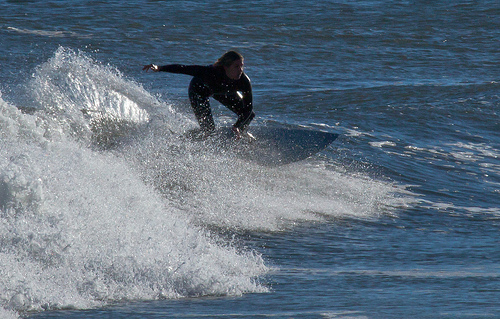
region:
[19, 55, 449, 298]
The wave is breaking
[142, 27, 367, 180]
Person surfing in the ocean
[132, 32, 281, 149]
Person wearing a wet suit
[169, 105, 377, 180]
Surfboard is blue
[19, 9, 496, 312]
The water is blue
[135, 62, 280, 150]
The wet suit is black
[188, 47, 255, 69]
Surfer has long hair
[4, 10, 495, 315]
Photo taken during the day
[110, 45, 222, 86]
Right arm is outstretched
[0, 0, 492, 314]
It's a sunny day out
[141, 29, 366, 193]
a person surfing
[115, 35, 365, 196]
a person on a surfboard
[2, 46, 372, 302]
the waves are large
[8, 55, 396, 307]
the waves are white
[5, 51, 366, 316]
waves in the ocean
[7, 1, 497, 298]
the ocean is undulating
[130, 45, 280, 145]
the person wearing a wetsuit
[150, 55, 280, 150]
the wetsuit is dark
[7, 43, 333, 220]
the waves are splashing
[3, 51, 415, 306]
the waves are frothy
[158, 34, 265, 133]
man is on surfboard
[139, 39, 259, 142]
man wears black swimsuit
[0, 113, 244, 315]
man rides choppy wave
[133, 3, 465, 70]
water is calm behind wave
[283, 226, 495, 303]
water is calm in front of wave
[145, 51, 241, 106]
right arm is outstretched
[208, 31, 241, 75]
man has light hair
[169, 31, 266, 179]
man is surfing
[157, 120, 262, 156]
feet are spread apart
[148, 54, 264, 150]
man does not wear shoes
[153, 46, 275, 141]
Man wearing black is surfing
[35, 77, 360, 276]
Crest of wave is white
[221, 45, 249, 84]
Man's face looking straight ahead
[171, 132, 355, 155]
Board is short and white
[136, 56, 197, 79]
Right arm held out behind man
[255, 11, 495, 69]
Water behind man is calm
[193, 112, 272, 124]
Man's knees are bent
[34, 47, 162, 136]
Wave is crashing upon itself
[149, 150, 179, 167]
Small specks of water in wave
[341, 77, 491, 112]
Wave swell in background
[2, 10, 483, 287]
man surfing in a wet suit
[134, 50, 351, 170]
surfing in a wet suit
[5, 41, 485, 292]
surfing waves in a wet suit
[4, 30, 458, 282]
surfing white waves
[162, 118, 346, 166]
blue surf board in the water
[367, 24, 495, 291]
blue ocean water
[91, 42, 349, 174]
kneeling on a surf board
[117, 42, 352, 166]
surfing in a black wet suit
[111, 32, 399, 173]
surfing in a dry suit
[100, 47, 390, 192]
black dry suit